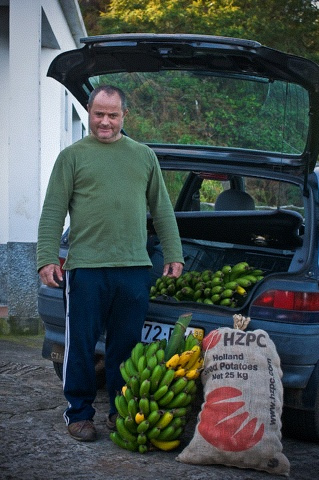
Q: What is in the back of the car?
A: Bananas.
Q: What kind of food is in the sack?
A: Potatoes.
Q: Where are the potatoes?
A: In the burlap sack.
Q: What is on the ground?
A: Potatoes bag.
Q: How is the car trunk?
A: Open.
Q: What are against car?
A: Green bananas.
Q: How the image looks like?
A: Good.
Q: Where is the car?
A: In Front of the trees.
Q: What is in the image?
A: A blue car with hatchback trunk.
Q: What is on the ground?
A: Potatoes bag.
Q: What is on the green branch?
A: Bunch of bananas.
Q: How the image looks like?
A: Good.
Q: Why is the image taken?
A: Remembrance.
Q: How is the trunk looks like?
A: Opened.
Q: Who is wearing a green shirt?
A: The man.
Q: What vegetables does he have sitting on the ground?
A: Bananas and potatoes.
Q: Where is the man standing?
A: Behind his car.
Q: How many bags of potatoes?
A: One.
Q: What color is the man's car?
A: Blue.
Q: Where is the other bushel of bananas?
A: In the car.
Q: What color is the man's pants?
A: Blue pants.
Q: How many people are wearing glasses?
A: None.